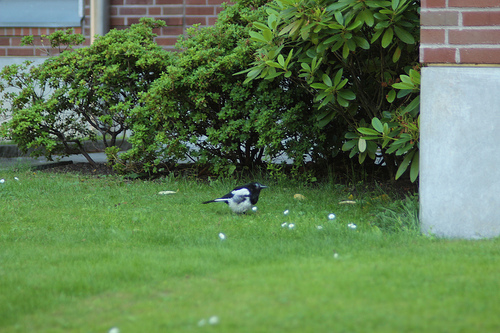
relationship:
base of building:
[419, 65, 499, 238] [417, 0, 497, 237]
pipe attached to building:
[86, 3, 113, 45] [6, 0, 496, 190]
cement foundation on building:
[6, 68, 497, 240] [0, 0, 498, 238]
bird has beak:
[202, 179, 268, 214] [259, 184, 266, 189]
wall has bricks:
[421, 2, 498, 195] [423, 3, 496, 60]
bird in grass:
[202, 181, 267, 217] [0, 170, 500, 332]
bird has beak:
[202, 181, 267, 217] [258, 179, 268, 193]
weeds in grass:
[279, 204, 358, 259] [0, 170, 500, 332]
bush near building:
[0, 11, 174, 175] [0, 0, 498, 238]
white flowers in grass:
[216, 194, 345, 260] [35, 175, 477, 320]